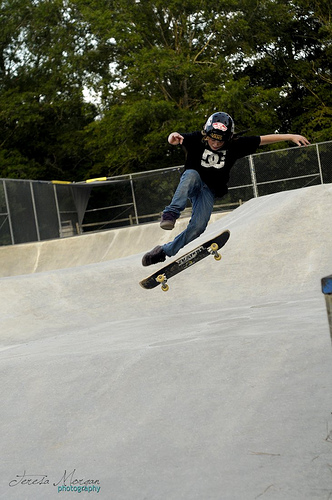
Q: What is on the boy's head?
A: A helmet.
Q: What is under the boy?
A: A skateboard.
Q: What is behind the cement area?
A: A fence.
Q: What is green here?
A: The trees.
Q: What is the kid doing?
A: Skating.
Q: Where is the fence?
A: Behind the boy.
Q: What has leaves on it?
A: The trees.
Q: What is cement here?
A: The ground.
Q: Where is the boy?
A: Skatepark.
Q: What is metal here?
A: The fence.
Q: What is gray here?
A: The ground.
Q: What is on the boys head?
A: A helmet.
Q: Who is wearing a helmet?
A: SKATEBOARDER.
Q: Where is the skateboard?
A: Air.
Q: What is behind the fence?
A: Trees.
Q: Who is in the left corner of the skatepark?
A: No people.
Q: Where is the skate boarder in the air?
A: Above the skate board.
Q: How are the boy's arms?
A: Extended.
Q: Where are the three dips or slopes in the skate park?
A: Concrete on the left.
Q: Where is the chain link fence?
A: Around the skate park.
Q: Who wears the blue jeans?
A: Boy.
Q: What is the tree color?
A: Green.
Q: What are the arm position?
A: Sides.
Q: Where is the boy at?
A: Skate park.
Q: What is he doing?
A: Skateboard tricks.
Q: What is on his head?
A: Helmet.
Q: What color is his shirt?
A: Black.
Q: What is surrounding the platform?
A: A gate.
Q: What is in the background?
A: Trees.